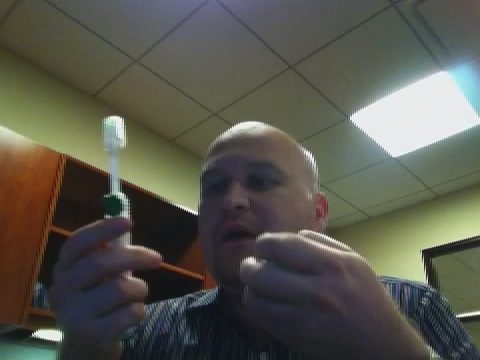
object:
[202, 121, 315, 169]
bald head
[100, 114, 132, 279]
toothbrush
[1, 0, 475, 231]
ceiling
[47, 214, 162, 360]
hand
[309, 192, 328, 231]
left ear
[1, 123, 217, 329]
cabinet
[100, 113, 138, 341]
white stick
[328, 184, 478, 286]
wall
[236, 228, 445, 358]
hand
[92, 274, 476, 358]
shirt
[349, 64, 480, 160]
light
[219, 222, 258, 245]
mouth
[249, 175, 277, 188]
eyes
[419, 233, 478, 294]
frame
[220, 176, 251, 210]
nose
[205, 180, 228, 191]
eyes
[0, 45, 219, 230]
wall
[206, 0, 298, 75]
trim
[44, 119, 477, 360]
man